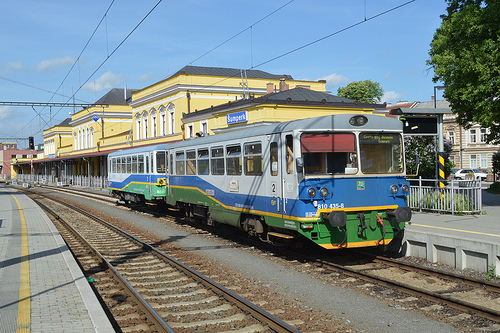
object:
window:
[222, 158, 242, 175]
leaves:
[455, 76, 460, 81]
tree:
[426, 0, 499, 149]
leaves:
[441, 30, 448, 33]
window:
[244, 140, 265, 154]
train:
[107, 112, 409, 254]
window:
[360, 131, 404, 177]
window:
[196, 148, 207, 158]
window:
[174, 160, 188, 174]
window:
[266, 141, 279, 176]